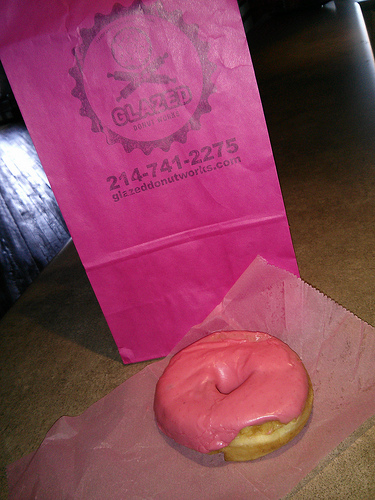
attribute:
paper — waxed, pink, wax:
[21, 244, 373, 500]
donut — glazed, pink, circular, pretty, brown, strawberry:
[151, 319, 318, 471]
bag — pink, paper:
[3, 2, 315, 369]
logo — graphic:
[66, 5, 226, 168]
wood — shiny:
[3, 120, 62, 298]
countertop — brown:
[10, 80, 373, 499]